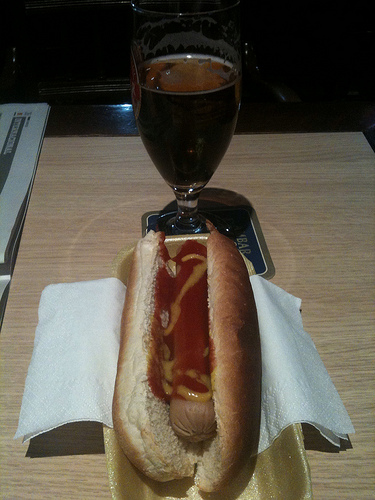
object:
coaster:
[141, 204, 276, 280]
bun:
[112, 223, 262, 498]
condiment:
[145, 230, 222, 401]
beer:
[130, 53, 240, 199]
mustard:
[174, 358, 202, 383]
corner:
[37, 100, 53, 114]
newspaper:
[0, 102, 53, 326]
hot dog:
[112, 227, 261, 497]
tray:
[102, 234, 313, 498]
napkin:
[12, 274, 354, 458]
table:
[3, 128, 372, 498]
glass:
[129, 1, 244, 235]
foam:
[143, 46, 239, 74]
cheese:
[158, 255, 206, 333]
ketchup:
[187, 288, 204, 349]